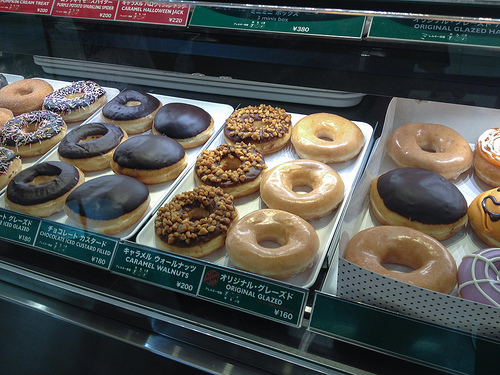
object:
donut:
[0, 77, 53, 116]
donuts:
[385, 118, 473, 180]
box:
[336, 93, 499, 346]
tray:
[135, 99, 375, 292]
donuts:
[151, 102, 215, 149]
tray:
[0, 84, 238, 244]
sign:
[199, 263, 310, 330]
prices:
[174, 279, 195, 293]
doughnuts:
[342, 225, 457, 302]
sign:
[113, 0, 189, 28]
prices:
[89, 255, 106, 265]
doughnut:
[466, 181, 499, 251]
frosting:
[471, 188, 499, 241]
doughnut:
[60, 173, 148, 235]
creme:
[64, 174, 149, 219]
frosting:
[64, 173, 149, 221]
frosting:
[114, 134, 184, 171]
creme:
[113, 133, 186, 169]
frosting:
[156, 102, 209, 138]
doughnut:
[4, 160, 87, 218]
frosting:
[9, 161, 81, 199]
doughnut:
[55, 120, 129, 172]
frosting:
[58, 121, 123, 158]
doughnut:
[42, 80, 108, 122]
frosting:
[46, 81, 104, 112]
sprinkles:
[42, 81, 106, 116]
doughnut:
[2, 107, 68, 158]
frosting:
[3, 112, 69, 146]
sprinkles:
[0, 107, 67, 149]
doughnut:
[225, 208, 321, 279]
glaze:
[226, 207, 329, 281]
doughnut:
[258, 159, 344, 222]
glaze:
[260, 158, 348, 225]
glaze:
[291, 109, 370, 168]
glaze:
[388, 121, 475, 169]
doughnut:
[155, 188, 237, 259]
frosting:
[153, 189, 234, 246]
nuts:
[160, 189, 232, 246]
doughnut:
[192, 142, 268, 199]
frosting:
[197, 144, 263, 189]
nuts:
[196, 142, 266, 184]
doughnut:
[223, 103, 293, 156]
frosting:
[222, 106, 290, 143]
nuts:
[225, 104, 291, 140]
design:
[336, 257, 499, 340]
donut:
[469, 119, 500, 191]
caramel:
[483, 131, 499, 160]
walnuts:
[479, 126, 499, 162]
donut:
[110, 134, 189, 185]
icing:
[114, 133, 183, 169]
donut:
[99, 87, 164, 134]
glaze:
[102, 89, 158, 117]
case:
[2, 0, 498, 372]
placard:
[187, 3, 368, 42]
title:
[249, 8, 301, 18]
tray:
[24, 46, 363, 111]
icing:
[224, 106, 290, 144]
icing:
[45, 81, 102, 109]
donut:
[453, 243, 499, 312]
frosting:
[453, 244, 499, 319]